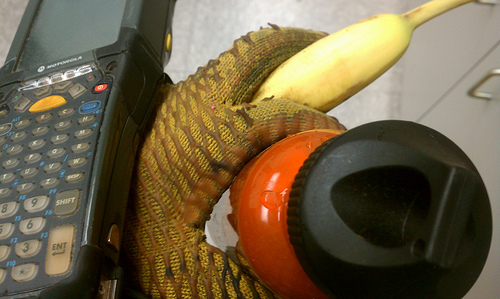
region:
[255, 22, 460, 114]
The banana is yellow.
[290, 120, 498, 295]
The lid is black.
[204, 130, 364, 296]
The cup is orange.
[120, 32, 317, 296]
The cover is tan.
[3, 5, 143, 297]
The scanner is black.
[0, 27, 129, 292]
The scanner has grey buttons on it.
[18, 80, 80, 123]
A big yellow button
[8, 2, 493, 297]
The screen is blank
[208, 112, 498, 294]
The mug is next to the banana.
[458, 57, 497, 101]
The handle is silver.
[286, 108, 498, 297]
black plastic cover of travel mug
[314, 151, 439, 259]
oblong indentation on plastic travel mug cover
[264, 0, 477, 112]
ripe pale yellow banana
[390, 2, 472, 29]
stalk of yellow banana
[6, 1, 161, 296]
black Motorola work machine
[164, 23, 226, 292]
yellow patterned work glove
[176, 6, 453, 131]
yellow work glove gripping a banana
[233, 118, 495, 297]
top of orange and black travel mug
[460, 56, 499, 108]
shiny metal cabinet handle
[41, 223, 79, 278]
white enter button on work machine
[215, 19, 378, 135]
brown banana knitted pouch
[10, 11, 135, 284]
black Motorola cell phone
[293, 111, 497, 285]
black plastic bottle lid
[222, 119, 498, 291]
red and black water bottle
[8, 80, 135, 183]
orange button on a cell phone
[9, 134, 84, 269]
blue printed numbers and letters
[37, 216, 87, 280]
dirty brown Enter button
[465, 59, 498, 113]
steal cabinet door handle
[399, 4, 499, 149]
white cabinate door with handle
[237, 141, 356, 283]
wet and red plastic container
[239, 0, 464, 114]
a yellow banana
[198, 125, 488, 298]
a red and black drink thermos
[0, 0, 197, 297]
a black phone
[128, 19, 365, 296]
a yellow and brown glove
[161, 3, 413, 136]
a floor visible under a banana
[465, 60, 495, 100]
a handle on a cupboard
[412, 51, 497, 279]
a white cupboard door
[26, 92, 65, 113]
a yellow button on a phone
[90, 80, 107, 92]
a red button on a phone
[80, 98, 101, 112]
a blue button on a phone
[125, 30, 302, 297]
The cover is brown.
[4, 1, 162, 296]
The device is black.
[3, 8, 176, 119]
The screen is on.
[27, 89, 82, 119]
The button is yellow.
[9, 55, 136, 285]
The buttons are grey.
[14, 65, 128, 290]
Many buttons are on the devise.